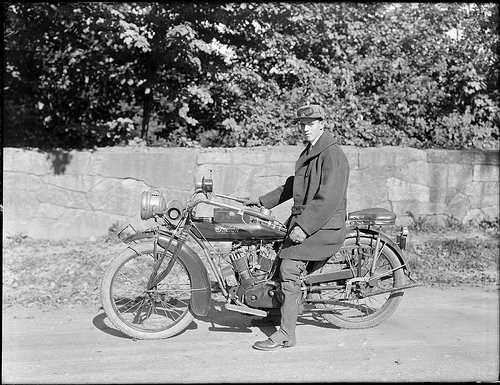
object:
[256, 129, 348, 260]
coat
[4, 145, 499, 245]
wall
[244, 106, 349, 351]
man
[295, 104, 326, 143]
head